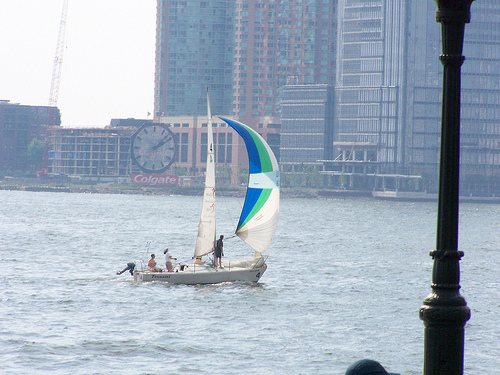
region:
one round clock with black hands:
[129, 121, 178, 173]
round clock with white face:
[128, 117, 180, 174]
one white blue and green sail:
[213, 108, 286, 262]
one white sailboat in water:
[124, 93, 282, 290]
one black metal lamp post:
[416, 0, 472, 372]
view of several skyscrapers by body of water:
[142, 2, 489, 196]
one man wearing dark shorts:
[211, 232, 231, 275]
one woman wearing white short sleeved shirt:
[160, 248, 182, 270]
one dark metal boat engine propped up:
[115, 255, 138, 284]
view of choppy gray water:
[35, 300, 232, 360]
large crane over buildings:
[4, 2, 171, 189]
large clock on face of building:
[40, 111, 248, 196]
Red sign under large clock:
[114, 118, 188, 195]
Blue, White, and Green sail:
[209, 83, 283, 289]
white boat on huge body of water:
[94, 214, 293, 301]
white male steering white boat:
[106, 83, 294, 294]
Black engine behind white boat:
[108, 254, 278, 290]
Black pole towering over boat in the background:
[4, 1, 496, 369]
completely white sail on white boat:
[118, 83, 285, 288]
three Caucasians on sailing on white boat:
[108, 80, 285, 290]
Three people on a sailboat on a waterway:
[118, 79, 283, 294]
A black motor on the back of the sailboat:
[114, 260, 135, 277]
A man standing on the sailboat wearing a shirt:
[211, 235, 223, 269]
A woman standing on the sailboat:
[158, 247, 179, 273]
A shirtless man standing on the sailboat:
[143, 252, 159, 272]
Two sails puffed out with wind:
[192, 83, 284, 261]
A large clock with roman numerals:
[126, 120, 178, 172]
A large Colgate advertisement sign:
[129, 172, 180, 188]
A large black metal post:
[417, 0, 473, 373]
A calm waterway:
[2, 187, 497, 372]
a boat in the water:
[141, 109, 343, 371]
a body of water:
[119, 306, 326, 364]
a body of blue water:
[79, 320, 133, 362]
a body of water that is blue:
[136, 297, 288, 370]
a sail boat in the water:
[116, 119, 401, 372]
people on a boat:
[125, 157, 330, 332]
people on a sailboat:
[69, 181, 273, 302]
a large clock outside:
[114, 82, 199, 200]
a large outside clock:
[115, 99, 212, 199]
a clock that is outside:
[75, 82, 388, 364]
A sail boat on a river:
[92, 89, 297, 296]